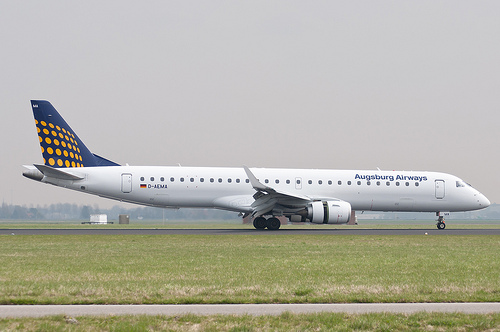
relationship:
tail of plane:
[24, 99, 119, 187] [19, 98, 491, 231]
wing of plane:
[211, 168, 315, 225] [19, 98, 491, 231]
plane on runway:
[19, 98, 491, 231] [1, 227, 500, 237]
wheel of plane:
[437, 223, 448, 230] [19, 98, 491, 231]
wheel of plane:
[267, 216, 280, 230] [19, 98, 491, 231]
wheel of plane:
[253, 216, 267, 230] [19, 98, 491, 231]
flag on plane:
[139, 183, 149, 190] [19, 98, 491, 231]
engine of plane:
[304, 199, 353, 225] [19, 98, 491, 231]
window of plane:
[150, 177, 156, 182] [19, 98, 491, 231]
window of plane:
[179, 176, 184, 182] [19, 98, 491, 231]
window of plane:
[236, 177, 241, 184] [19, 98, 491, 231]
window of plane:
[285, 178, 291, 183] [19, 98, 491, 231]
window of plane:
[365, 180, 371, 187] [19, 98, 491, 231]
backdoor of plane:
[119, 172, 133, 194] [19, 98, 491, 231]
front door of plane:
[434, 179, 446, 199] [19, 98, 491, 231]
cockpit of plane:
[454, 180, 471, 189] [19, 98, 491, 231]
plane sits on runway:
[19, 98, 491, 231] [1, 227, 500, 237]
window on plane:
[179, 176, 184, 182] [19, 98, 491, 231]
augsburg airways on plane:
[353, 174, 428, 180] [19, 98, 491, 231]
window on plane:
[236, 177, 241, 184] [19, 98, 491, 231]